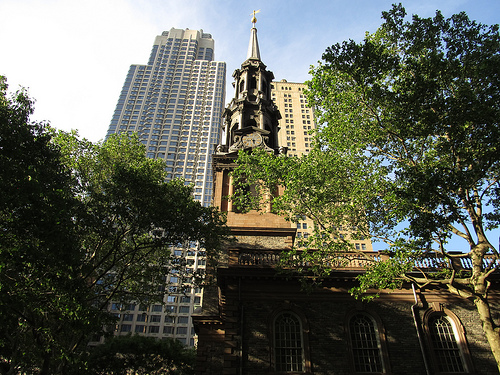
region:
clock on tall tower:
[232, 122, 272, 159]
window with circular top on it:
[266, 307, 316, 373]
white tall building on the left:
[153, 45, 213, 177]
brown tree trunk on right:
[460, 268, 497, 338]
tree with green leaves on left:
[8, 124, 43, 188]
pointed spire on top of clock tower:
[242, 4, 269, 29]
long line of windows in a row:
[163, 78, 199, 169]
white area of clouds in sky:
[51, 17, 115, 57]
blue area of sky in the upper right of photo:
[310, 4, 356, 41]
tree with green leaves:
[386, 75, 474, 117]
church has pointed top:
[225, 18, 266, 60]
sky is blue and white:
[75, 10, 477, 84]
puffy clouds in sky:
[37, 24, 132, 105]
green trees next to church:
[7, 143, 165, 370]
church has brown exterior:
[195, 220, 427, 372]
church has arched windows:
[278, 314, 473, 366]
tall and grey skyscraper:
[90, 11, 215, 289]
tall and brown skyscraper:
[281, 83, 369, 257]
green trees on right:
[332, 35, 496, 259]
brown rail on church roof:
[304, 247, 492, 281]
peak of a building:
[212, 6, 297, 249]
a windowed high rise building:
[77, 25, 226, 353]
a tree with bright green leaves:
[233, 3, 498, 365]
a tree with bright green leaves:
[1, 76, 228, 373]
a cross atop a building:
[249, 8, 261, 22]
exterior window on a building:
[265, 301, 310, 371]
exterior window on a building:
[339, 305, 391, 374]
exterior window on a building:
[415, 300, 477, 374]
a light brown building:
[263, 78, 373, 269]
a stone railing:
[222, 245, 498, 276]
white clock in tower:
[239, 132, 260, 150]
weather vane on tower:
[247, 7, 260, 16]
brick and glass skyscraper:
[86, 25, 228, 350]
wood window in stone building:
[272, 315, 304, 367]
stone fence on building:
[243, 248, 499, 269]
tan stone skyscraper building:
[271, 78, 372, 251]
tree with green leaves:
[234, 5, 499, 372]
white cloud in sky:
[3, 0, 200, 141]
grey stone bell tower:
[236, 72, 271, 95]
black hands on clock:
[248, 137, 256, 145]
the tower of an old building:
[198, 2, 498, 368]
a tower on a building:
[205, 11, 311, 276]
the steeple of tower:
[228, 5, 269, 73]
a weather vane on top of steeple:
[241, 5, 270, 64]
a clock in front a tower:
[231, 122, 270, 154]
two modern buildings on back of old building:
[58, 7, 385, 364]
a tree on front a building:
[271, 8, 499, 373]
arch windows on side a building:
[260, 300, 482, 372]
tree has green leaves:
[204, 2, 499, 372]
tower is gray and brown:
[198, 7, 306, 251]